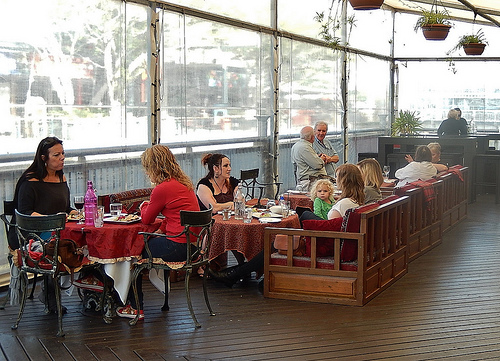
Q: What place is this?
A: It is a restaurant.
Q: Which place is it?
A: It is a restaurant.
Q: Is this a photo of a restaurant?
A: Yes, it is showing a restaurant.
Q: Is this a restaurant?
A: Yes, it is a restaurant.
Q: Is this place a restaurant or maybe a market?
A: It is a restaurant.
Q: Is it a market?
A: No, it is a restaurant.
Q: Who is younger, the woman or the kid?
A: The kid is younger than the woman.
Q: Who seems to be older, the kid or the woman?
A: The woman is older than the kid.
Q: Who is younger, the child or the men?
A: The child is younger than the men.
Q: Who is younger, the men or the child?
A: The child is younger than the men.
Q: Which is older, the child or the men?
A: The men is older than the child.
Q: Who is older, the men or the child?
A: The men is older than the child.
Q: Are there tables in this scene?
A: Yes, there is a table.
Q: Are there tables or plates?
A: Yes, there is a table.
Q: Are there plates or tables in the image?
A: Yes, there is a table.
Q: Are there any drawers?
A: No, there are no drawers.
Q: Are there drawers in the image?
A: No, there are no drawers.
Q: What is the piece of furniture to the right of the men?
A: The piece of furniture is a table.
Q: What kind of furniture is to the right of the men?
A: The piece of furniture is a table.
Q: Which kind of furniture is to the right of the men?
A: The piece of furniture is a table.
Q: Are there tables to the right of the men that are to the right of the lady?
A: Yes, there is a table to the right of the men.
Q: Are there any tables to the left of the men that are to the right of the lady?
A: No, the table is to the right of the men.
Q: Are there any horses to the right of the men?
A: No, there is a table to the right of the men.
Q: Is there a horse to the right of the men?
A: No, there is a table to the right of the men.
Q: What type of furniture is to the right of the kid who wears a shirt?
A: The piece of furniture is a table.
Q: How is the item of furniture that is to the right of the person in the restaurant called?
A: The piece of furniture is a table.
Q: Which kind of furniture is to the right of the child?
A: The piece of furniture is a table.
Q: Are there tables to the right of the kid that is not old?
A: Yes, there is a table to the right of the kid.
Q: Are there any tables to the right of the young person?
A: Yes, there is a table to the right of the kid.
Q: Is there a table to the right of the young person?
A: Yes, there is a table to the right of the kid.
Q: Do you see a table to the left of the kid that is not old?
A: No, the table is to the right of the kid.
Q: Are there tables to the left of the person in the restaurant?
A: No, the table is to the right of the kid.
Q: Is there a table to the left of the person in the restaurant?
A: No, the table is to the right of the kid.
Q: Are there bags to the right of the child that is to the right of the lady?
A: No, there is a table to the right of the kid.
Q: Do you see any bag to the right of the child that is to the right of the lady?
A: No, there is a table to the right of the kid.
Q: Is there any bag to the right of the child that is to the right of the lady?
A: No, there is a table to the right of the kid.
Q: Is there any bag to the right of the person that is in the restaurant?
A: No, there is a table to the right of the kid.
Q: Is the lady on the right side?
A: No, the lady is on the left of the image.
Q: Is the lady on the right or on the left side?
A: The lady is on the left of the image.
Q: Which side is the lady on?
A: The lady is on the left of the image.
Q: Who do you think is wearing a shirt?
A: The lady is wearing a shirt.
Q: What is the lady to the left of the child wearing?
A: The lady is wearing a shirt.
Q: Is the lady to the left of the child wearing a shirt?
A: Yes, the lady is wearing a shirt.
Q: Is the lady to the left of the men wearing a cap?
A: No, the lady is wearing a shirt.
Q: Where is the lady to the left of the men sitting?
A: The lady is sitting at the table.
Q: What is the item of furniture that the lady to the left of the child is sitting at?
A: The piece of furniture is a table.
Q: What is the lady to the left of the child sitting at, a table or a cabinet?
A: The lady is sitting at a table.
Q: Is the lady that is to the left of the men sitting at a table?
A: Yes, the lady is sitting at a table.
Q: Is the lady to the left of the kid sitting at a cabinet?
A: No, the lady is sitting at a table.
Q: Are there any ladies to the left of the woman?
A: Yes, there is a lady to the left of the woman.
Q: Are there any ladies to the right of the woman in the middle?
A: No, the lady is to the left of the woman.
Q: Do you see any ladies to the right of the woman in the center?
A: No, the lady is to the left of the woman.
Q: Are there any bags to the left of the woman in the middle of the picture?
A: No, there is a lady to the left of the woman.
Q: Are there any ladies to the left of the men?
A: Yes, there is a lady to the left of the men.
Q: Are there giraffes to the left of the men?
A: No, there is a lady to the left of the men.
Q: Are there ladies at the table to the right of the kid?
A: Yes, there is a lady at the table.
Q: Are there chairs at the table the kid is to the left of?
A: No, there is a lady at the table.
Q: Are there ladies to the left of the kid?
A: Yes, there is a lady to the left of the kid.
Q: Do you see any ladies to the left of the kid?
A: Yes, there is a lady to the left of the kid.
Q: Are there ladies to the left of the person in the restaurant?
A: Yes, there is a lady to the left of the kid.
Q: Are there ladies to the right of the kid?
A: No, the lady is to the left of the kid.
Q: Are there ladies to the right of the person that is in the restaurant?
A: No, the lady is to the left of the kid.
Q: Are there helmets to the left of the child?
A: No, there is a lady to the left of the child.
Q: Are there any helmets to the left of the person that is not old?
A: No, there is a lady to the left of the child.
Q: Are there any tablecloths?
A: Yes, there is a tablecloth.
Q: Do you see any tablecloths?
A: Yes, there is a tablecloth.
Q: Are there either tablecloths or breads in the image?
A: Yes, there is a tablecloth.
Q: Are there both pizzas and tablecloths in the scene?
A: No, there is a tablecloth but no pizzas.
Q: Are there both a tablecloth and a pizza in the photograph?
A: No, there is a tablecloth but no pizzas.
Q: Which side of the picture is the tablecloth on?
A: The tablecloth is on the left of the image.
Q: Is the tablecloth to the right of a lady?
A: Yes, the tablecloth is to the right of a lady.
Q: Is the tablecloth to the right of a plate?
A: No, the tablecloth is to the right of a lady.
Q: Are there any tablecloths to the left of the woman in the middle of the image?
A: Yes, there is a tablecloth to the left of the woman.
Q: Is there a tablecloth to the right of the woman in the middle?
A: No, the tablecloth is to the left of the woman.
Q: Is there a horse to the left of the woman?
A: No, there is a tablecloth to the left of the woman.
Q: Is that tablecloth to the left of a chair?
A: No, the tablecloth is to the left of the woman.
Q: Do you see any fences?
A: No, there are no fences.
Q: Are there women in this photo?
A: Yes, there is a woman.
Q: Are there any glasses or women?
A: Yes, there is a woman.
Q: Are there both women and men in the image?
A: Yes, there are both a woman and a man.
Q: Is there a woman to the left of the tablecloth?
A: No, the woman is to the right of the tablecloth.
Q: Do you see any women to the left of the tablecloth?
A: No, the woman is to the right of the tablecloth.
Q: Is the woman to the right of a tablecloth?
A: Yes, the woman is to the right of a tablecloth.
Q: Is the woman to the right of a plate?
A: No, the woman is to the right of a tablecloth.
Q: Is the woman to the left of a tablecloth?
A: No, the woman is to the right of a tablecloth.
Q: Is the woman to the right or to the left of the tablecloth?
A: The woman is to the right of the tablecloth.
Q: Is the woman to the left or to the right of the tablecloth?
A: The woman is to the right of the tablecloth.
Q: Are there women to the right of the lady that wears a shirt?
A: Yes, there is a woman to the right of the lady.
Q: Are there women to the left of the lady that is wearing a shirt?
A: No, the woman is to the right of the lady.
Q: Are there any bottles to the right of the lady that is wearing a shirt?
A: No, there is a woman to the right of the lady.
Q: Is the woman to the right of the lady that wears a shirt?
A: Yes, the woman is to the right of the lady.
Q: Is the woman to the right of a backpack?
A: No, the woman is to the right of the lady.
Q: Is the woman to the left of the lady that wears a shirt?
A: No, the woman is to the right of the lady.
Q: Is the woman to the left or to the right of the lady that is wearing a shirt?
A: The woman is to the right of the lady.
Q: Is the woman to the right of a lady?
A: Yes, the woman is to the right of a lady.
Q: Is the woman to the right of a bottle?
A: No, the woman is to the right of a lady.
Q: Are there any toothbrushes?
A: No, there are no toothbrushes.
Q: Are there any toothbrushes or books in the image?
A: No, there are no toothbrushes or books.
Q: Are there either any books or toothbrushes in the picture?
A: No, there are no toothbrushes or books.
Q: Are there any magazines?
A: No, there are no magazines.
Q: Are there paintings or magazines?
A: No, there are no magazines or paintings.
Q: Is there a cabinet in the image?
A: No, there are no cabinets.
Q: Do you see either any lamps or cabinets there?
A: No, there are no cabinets or lamps.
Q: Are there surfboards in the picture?
A: No, there are no surfboards.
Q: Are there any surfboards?
A: No, there are no surfboards.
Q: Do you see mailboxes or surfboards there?
A: No, there are no surfboards or mailboxes.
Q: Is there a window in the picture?
A: Yes, there is a window.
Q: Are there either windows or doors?
A: Yes, there is a window.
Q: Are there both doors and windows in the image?
A: No, there is a window but no doors.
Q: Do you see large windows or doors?
A: Yes, there is a large window.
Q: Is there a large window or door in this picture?
A: Yes, there is a large window.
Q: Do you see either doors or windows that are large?
A: Yes, the window is large.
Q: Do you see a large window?
A: Yes, there is a large window.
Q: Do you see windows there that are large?
A: Yes, there is a window that is large.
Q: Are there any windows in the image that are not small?
A: Yes, there is a large window.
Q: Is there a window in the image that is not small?
A: Yes, there is a large window.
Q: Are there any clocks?
A: No, there are no clocks.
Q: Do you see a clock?
A: No, there are no clocks.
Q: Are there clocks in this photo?
A: No, there are no clocks.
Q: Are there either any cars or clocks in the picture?
A: No, there are no clocks or cars.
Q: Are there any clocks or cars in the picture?
A: No, there are no clocks or cars.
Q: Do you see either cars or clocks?
A: No, there are no clocks or cars.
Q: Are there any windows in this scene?
A: Yes, there is a window.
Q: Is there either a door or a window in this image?
A: Yes, there is a window.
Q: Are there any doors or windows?
A: Yes, there is a window.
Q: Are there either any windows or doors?
A: Yes, there is a window.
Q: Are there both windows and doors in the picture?
A: No, there is a window but no doors.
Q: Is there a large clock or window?
A: Yes, there is a large window.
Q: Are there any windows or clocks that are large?
A: Yes, the window is large.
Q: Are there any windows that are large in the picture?
A: Yes, there is a large window.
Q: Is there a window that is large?
A: Yes, there is a window that is large.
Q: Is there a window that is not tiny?
A: Yes, there is a large window.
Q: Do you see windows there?
A: Yes, there is a window.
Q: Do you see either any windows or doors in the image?
A: Yes, there is a window.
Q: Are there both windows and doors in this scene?
A: No, there is a window but no doors.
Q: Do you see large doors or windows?
A: Yes, there is a large window.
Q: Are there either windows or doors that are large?
A: Yes, the window is large.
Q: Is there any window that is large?
A: Yes, there is a window that is large.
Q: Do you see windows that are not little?
A: Yes, there is a large window.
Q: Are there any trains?
A: No, there are no trains.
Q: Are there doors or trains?
A: No, there are no trains or doors.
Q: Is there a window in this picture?
A: Yes, there is a window.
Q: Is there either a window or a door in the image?
A: Yes, there is a window.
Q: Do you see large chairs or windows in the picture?
A: Yes, there is a large window.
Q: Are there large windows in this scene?
A: Yes, there is a large window.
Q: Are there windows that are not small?
A: Yes, there is a large window.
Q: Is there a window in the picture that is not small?
A: Yes, there is a large window.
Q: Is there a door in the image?
A: No, there are no doors.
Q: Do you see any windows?
A: Yes, there is a window.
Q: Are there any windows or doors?
A: Yes, there is a window.